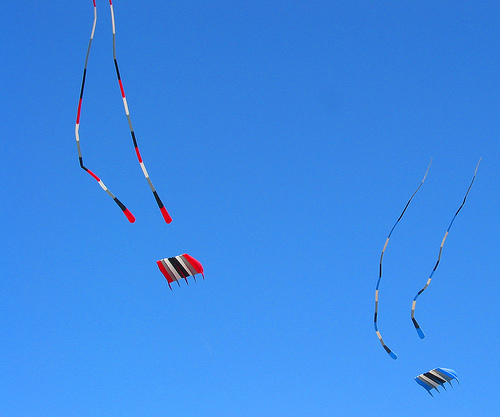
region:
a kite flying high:
[76, 3, 206, 290]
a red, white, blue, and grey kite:
[74, 6, 207, 288]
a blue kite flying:
[374, 168, 483, 395]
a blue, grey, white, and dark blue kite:
[374, 170, 479, 394]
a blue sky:
[1, 1, 497, 412]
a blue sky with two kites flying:
[4, 0, 497, 414]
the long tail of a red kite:
[75, 0, 172, 225]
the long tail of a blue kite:
[373, 169, 480, 356]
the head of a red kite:
[155, 252, 207, 289]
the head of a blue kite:
[414, 368, 460, 398]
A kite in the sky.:
[73, 3, 208, 293]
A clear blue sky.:
[1, 1, 499, 411]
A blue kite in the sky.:
[372, 153, 479, 395]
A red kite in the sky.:
[74, 2, 208, 291]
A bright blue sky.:
[0, 3, 497, 415]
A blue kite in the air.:
[373, 155, 483, 398]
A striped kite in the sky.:
[74, 0, 209, 291]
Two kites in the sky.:
[74, 0, 484, 400]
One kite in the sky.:
[372, 154, 484, 399]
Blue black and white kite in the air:
[372, 154, 484, 396]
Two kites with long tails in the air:
[75, 0, 486, 395]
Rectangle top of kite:
[413, 365, 459, 390]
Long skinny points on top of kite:
[166, 270, 208, 290]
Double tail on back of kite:
[376, 152, 485, 359]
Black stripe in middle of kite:
[155, 254, 207, 291]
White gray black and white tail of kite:
[73, 0, 173, 225]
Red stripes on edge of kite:
[154, 251, 204, 282]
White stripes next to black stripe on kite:
[155, 250, 206, 289]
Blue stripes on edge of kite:
[413, 365, 463, 396]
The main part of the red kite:
[151, 250, 214, 285]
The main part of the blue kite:
[415, 366, 457, 394]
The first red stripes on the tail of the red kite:
[122, 208, 173, 226]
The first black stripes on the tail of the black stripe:
[109, 193, 174, 208]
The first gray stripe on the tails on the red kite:
[97, 176, 159, 191]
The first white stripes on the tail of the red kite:
[83, 161, 163, 182]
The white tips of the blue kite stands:
[426, 145, 497, 200]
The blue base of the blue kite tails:
[379, 329, 439, 360]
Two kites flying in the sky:
[65, 9, 477, 394]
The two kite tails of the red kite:
[69, 11, 179, 232]